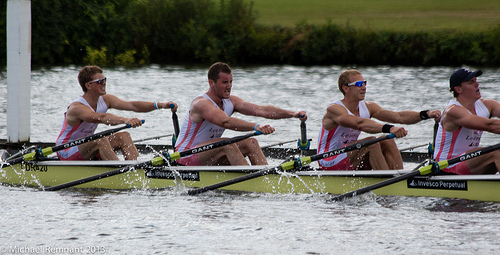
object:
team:
[53, 61, 500, 178]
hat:
[448, 66, 484, 93]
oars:
[326, 141, 499, 204]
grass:
[213, 1, 499, 34]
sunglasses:
[86, 77, 108, 86]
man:
[316, 69, 442, 171]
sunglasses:
[346, 79, 368, 89]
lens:
[354, 81, 363, 87]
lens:
[362, 80, 368, 87]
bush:
[31, 0, 500, 72]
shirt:
[53, 95, 110, 146]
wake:
[1, 66, 500, 255]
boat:
[2, 138, 499, 202]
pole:
[5, 0, 31, 142]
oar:
[0, 120, 146, 169]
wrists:
[251, 123, 260, 130]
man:
[55, 64, 179, 160]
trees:
[31, 0, 263, 70]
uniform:
[54, 96, 111, 162]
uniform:
[175, 95, 234, 166]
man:
[430, 67, 499, 175]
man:
[171, 62, 308, 167]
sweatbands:
[378, 123, 396, 134]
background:
[0, 1, 499, 254]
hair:
[72, 66, 107, 95]